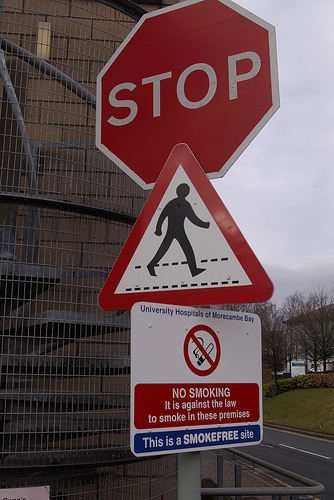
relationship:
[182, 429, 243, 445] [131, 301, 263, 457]
smokefree on no smoking sign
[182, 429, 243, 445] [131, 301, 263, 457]
smokefree part of no smoking sign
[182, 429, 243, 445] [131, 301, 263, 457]
smokefree visible on no smoking sign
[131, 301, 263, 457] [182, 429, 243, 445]
no smoking sign has smokefree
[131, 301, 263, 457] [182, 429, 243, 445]
no smoking sign features word smokefree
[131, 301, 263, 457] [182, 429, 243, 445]
no smoking sign has word smokefree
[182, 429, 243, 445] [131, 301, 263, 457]
smokefree written on no smoking sign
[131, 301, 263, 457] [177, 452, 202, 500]
no smoking sign on sign post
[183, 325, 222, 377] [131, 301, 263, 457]
no smoking picture on no smoking sign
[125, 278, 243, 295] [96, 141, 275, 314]
dotted line part of sign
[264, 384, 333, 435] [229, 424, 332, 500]
grass by road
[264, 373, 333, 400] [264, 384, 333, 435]
bushes are by grass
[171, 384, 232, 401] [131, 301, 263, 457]
no smoking part of no smoking sign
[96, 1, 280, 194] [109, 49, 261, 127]
stop sign has letters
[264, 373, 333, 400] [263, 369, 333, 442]
bushes are on hill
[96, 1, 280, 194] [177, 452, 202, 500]
stop sign on sign post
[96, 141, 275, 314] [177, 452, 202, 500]
sign on sign post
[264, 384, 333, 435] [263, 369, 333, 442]
grass on hill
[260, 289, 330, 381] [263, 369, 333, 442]
trees are near hill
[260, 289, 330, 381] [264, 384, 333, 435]
trees are near grass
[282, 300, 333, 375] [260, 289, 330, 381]
building behind trees